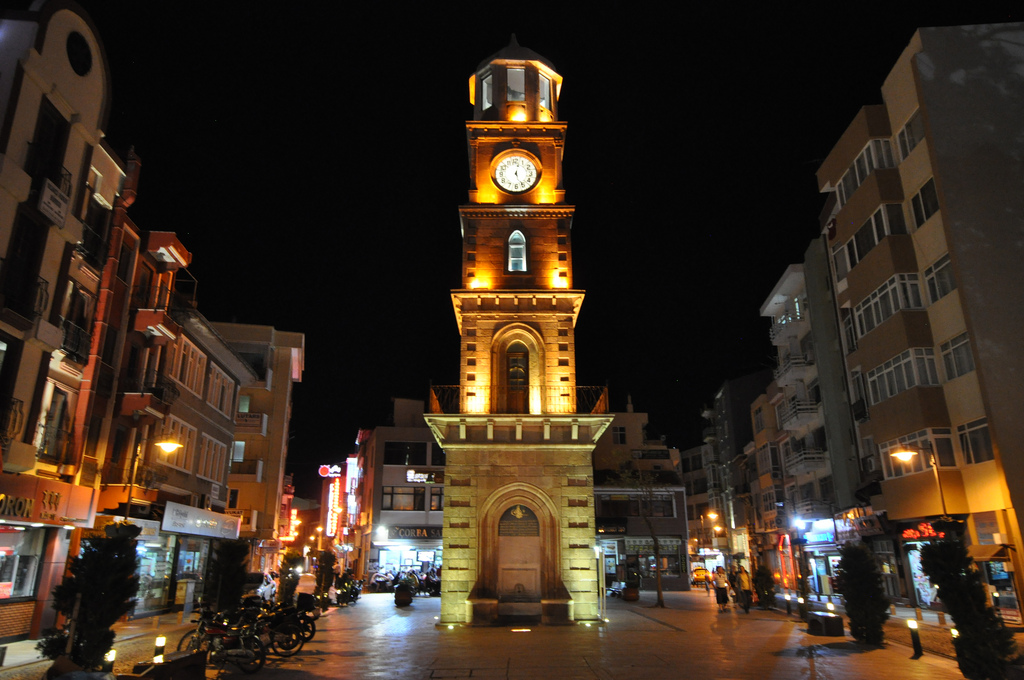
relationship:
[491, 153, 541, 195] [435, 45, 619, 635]
clock on tower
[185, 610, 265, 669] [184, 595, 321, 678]
bike chained to fence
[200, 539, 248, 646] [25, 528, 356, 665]
tree on sidewalk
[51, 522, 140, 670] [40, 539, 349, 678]
tree on sidewalk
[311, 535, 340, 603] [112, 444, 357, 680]
tree on sidewalk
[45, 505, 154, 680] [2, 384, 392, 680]
tree on sidewalk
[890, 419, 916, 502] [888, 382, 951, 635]
light on pole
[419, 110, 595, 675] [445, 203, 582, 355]
lights are on tower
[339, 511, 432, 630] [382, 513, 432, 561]
lights are blue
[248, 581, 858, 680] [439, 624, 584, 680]
sidewalk wet with rain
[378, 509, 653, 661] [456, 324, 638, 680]
light on tower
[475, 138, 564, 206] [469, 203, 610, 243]
face of clock white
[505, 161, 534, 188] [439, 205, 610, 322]
hands of clock are black in color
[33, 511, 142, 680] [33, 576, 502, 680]
tree on sidewalk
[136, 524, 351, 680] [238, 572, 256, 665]
bikes locked up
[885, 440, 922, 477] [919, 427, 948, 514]
light on pole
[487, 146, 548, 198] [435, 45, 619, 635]
clock on tower